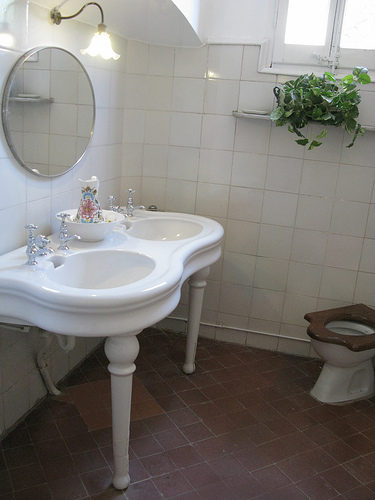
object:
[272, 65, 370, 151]
plant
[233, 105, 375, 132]
shelf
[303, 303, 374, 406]
toilet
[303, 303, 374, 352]
seat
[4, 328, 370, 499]
floor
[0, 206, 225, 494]
sink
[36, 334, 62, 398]
plumbing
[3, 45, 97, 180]
mirror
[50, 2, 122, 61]
light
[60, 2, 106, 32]
neck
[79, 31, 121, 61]
shade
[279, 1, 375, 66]
window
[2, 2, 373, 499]
bathroom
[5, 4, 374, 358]
walls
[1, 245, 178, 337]
basins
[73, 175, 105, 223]
pitcher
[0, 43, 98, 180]
frame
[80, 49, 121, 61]
edge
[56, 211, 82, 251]
faucets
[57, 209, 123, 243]
basin